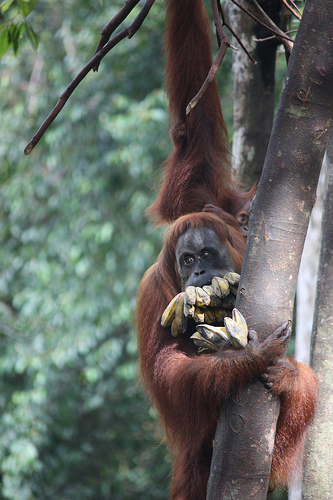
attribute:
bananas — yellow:
[158, 272, 243, 339]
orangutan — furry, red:
[134, 0, 321, 500]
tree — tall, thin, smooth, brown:
[204, 0, 333, 500]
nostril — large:
[194, 271, 200, 277]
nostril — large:
[199, 269, 207, 277]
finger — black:
[275, 318, 291, 338]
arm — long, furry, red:
[157, 331, 281, 404]